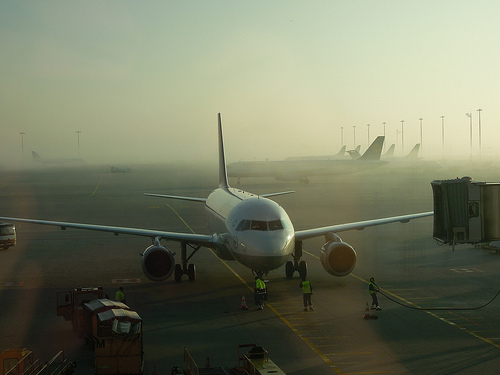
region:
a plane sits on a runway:
[0, 113, 435, 290]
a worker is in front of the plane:
[247, 275, 274, 310]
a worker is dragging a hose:
[362, 274, 387, 309]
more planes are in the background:
[216, 137, 452, 187]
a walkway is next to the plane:
[428, 173, 498, 250]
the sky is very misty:
[7, 2, 495, 177]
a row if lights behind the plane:
[325, 105, 492, 162]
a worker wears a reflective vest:
[294, 273, 321, 313]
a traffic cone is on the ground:
[230, 291, 250, 310]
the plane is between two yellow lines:
[162, 199, 499, 366]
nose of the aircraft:
[259, 236, 294, 281]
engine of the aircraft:
[134, 229, 186, 293]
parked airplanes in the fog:
[246, 141, 428, 196]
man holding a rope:
[355, 270, 408, 325]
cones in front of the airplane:
[234, 291, 257, 320]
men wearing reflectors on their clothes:
[245, 272, 393, 317]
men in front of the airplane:
[245, 270, 385, 315]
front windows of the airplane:
[224, 208, 299, 233]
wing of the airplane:
[8, 211, 219, 258]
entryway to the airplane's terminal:
[434, 161, 499, 243]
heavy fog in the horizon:
[80, 91, 355, 122]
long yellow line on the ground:
[271, 320, 331, 350]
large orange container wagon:
[90, 305, 160, 355]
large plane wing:
[315, 231, 365, 291]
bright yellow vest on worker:
[285, 275, 315, 305]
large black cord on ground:
[372, 283, 499, 328]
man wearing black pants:
[294, 287, 333, 313]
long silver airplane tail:
[202, 109, 245, 192]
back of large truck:
[1, 221, 26, 249]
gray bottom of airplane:
[225, 249, 297, 273]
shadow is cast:
[193, 272, 281, 357]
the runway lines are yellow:
[384, 278, 473, 343]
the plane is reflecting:
[173, 134, 302, 291]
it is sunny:
[8, 57, 499, 369]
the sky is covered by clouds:
[20, 52, 226, 197]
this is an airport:
[12, 67, 497, 359]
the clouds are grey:
[61, 65, 137, 126]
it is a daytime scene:
[11, 64, 454, 371]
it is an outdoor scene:
[9, 56, 461, 370]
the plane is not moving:
[72, 70, 434, 332]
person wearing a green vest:
[355, 265, 398, 322]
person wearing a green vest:
[291, 263, 318, 327]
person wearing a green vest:
[246, 261, 275, 318]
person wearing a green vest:
[110, 273, 131, 315]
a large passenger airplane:
[0, 97, 445, 298]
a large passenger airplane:
[201, 123, 403, 200]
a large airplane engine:
[313, 226, 359, 294]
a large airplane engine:
[124, 230, 192, 295]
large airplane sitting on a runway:
[0, 103, 487, 295]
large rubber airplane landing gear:
[277, 239, 314, 290]